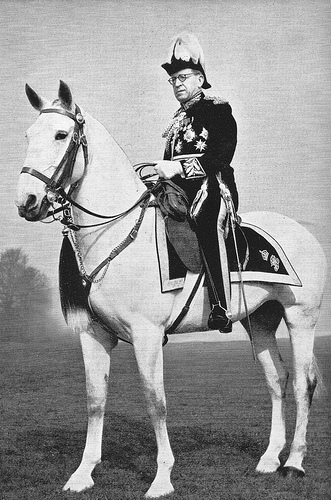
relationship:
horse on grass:
[13, 79, 328, 498] [3, 339, 329, 499]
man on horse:
[156, 32, 236, 332] [13, 79, 328, 498]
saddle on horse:
[155, 174, 232, 272] [13, 79, 328, 498]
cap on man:
[160, 32, 213, 85] [156, 32, 236, 332]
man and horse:
[156, 32, 236, 332] [13, 79, 328, 498]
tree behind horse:
[0, 245, 51, 345] [13, 79, 328, 498]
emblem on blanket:
[255, 248, 284, 269] [153, 198, 303, 290]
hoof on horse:
[64, 468, 97, 493] [13, 79, 328, 498]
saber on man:
[224, 187, 260, 364] [156, 32, 236, 332]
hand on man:
[150, 156, 181, 181] [156, 32, 236, 332]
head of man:
[170, 63, 206, 99] [156, 32, 236, 332]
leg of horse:
[126, 327, 176, 499] [13, 79, 328, 498]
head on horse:
[170, 63, 206, 99] [13, 79, 328, 498]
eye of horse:
[52, 129, 70, 143] [13, 79, 328, 498]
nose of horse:
[21, 192, 40, 213] [13, 79, 328, 498]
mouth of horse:
[35, 196, 51, 222] [13, 79, 328, 498]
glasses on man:
[167, 71, 197, 81] [156, 32, 236, 332]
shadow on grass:
[15, 403, 265, 478] [3, 339, 329, 499]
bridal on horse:
[24, 107, 85, 199] [13, 79, 328, 498]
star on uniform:
[192, 135, 206, 147] [169, 97, 240, 312]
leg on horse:
[126, 327, 176, 499] [13, 79, 328, 498]